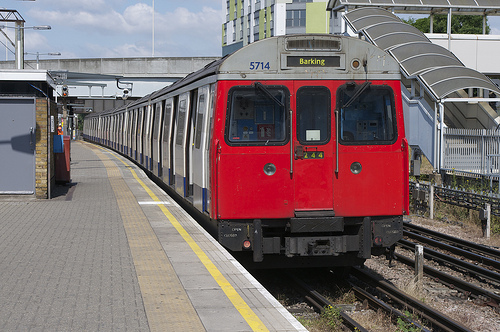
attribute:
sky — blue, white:
[1, 0, 221, 57]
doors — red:
[332, 87, 403, 214]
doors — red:
[215, 72, 304, 217]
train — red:
[76, 36, 416, 256]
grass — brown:
[331, 295, 361, 310]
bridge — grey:
[65, 57, 195, 77]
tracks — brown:
[276, 267, 468, 329]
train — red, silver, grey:
[82, 32, 409, 273]